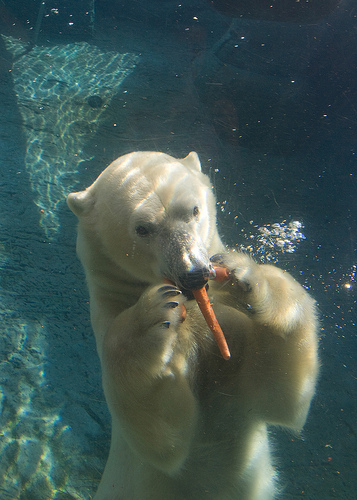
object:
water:
[0, 0, 356, 499]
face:
[76, 156, 234, 293]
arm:
[255, 264, 316, 434]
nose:
[180, 262, 212, 290]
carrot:
[163, 280, 186, 325]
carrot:
[207, 264, 230, 285]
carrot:
[192, 293, 231, 360]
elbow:
[263, 370, 313, 435]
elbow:
[133, 424, 193, 477]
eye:
[193, 205, 197, 215]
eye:
[135, 224, 149, 234]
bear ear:
[61, 186, 93, 217]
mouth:
[178, 270, 220, 293]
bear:
[66, 151, 322, 499]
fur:
[113, 155, 152, 217]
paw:
[124, 270, 190, 381]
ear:
[64, 190, 92, 223]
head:
[65, 148, 227, 303]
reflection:
[5, 40, 140, 251]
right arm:
[96, 358, 193, 475]